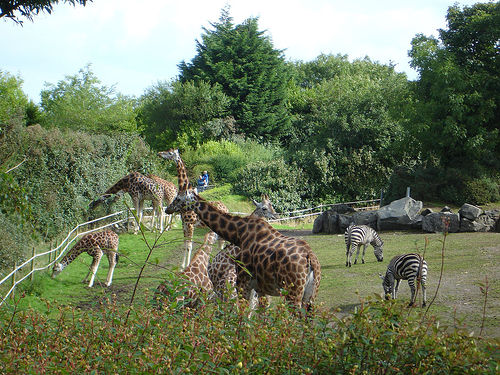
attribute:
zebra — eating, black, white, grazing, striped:
[382, 252, 430, 310]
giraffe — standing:
[156, 148, 225, 265]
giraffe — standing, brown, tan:
[164, 183, 323, 318]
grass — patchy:
[290, 232, 499, 344]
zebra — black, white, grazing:
[345, 226, 384, 263]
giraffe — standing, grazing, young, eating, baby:
[50, 230, 121, 288]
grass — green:
[7, 223, 207, 318]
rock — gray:
[376, 196, 424, 228]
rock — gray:
[421, 211, 460, 234]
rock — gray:
[457, 202, 483, 219]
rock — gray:
[351, 208, 379, 231]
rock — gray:
[321, 208, 336, 234]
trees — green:
[0, 3, 500, 212]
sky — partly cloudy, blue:
[0, 1, 500, 109]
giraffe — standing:
[152, 229, 215, 310]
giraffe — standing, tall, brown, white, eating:
[102, 173, 180, 233]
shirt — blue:
[197, 175, 207, 185]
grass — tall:
[0, 268, 499, 374]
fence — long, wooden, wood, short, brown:
[3, 205, 183, 308]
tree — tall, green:
[176, 2, 296, 139]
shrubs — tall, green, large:
[0, 126, 168, 276]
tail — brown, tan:
[308, 256, 321, 310]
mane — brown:
[190, 189, 246, 221]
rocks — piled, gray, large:
[311, 196, 498, 235]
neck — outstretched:
[192, 195, 246, 248]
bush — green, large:
[277, 75, 422, 203]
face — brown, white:
[163, 186, 196, 215]